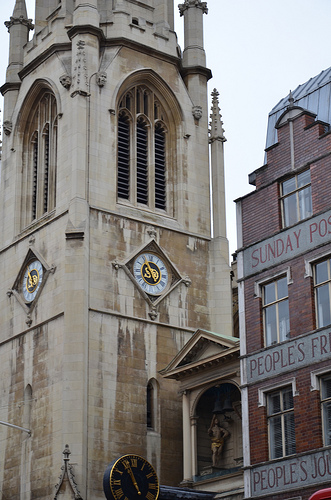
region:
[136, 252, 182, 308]
clock's hands are gold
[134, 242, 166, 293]
clock's hands are gold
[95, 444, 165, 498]
clock's face is black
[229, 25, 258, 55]
Part of the blue sky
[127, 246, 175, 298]
A big clock on the building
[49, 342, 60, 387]
Part of the building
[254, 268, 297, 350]
A window on the building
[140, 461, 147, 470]
A number on the clock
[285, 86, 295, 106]
The top part of the building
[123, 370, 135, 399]
Part of the brown wall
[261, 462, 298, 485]
Part of the sign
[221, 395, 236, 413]
A bell hanging from the ceiling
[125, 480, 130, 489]
Part of the blue clock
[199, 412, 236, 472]
a statue of a person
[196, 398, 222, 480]
a statue of a person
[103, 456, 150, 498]
the numbers are gold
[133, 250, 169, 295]
A clock is on the building.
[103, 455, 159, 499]
A clock is below the building.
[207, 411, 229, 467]
A statue is on the building.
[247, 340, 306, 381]
The word people's is on the building.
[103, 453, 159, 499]
The clock is black and gold.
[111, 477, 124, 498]
Roman numerals are on the clock.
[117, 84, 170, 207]
The building has a window.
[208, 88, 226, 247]
A spire is on the building.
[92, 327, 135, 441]
The building is made of stone.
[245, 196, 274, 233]
The building is made of bricks.